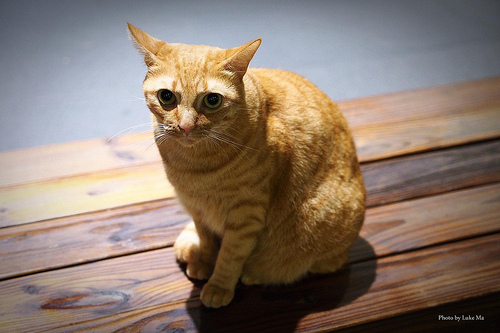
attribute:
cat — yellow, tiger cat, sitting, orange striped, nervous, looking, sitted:
[127, 22, 366, 308]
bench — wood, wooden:
[2, 76, 499, 331]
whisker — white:
[203, 128, 264, 155]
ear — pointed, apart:
[219, 38, 261, 86]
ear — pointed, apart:
[127, 22, 168, 62]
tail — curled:
[173, 219, 203, 263]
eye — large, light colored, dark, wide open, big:
[202, 92, 223, 110]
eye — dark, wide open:
[155, 89, 178, 107]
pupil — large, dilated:
[207, 93, 219, 105]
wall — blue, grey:
[1, 1, 499, 149]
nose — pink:
[178, 124, 196, 134]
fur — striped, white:
[143, 41, 369, 307]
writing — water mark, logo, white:
[436, 313, 486, 320]